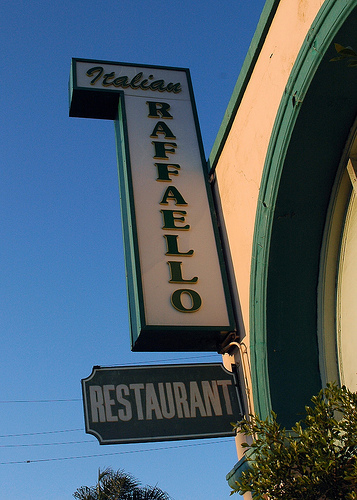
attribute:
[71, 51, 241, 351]
sign — shaped like a seven, green, white, restaurant, advertising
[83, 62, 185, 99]
italian — written in cursive, in cursive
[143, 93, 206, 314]
raffaello — written in print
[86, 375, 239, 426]
lettering — white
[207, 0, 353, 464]
building — green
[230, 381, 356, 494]
tree — green, tropical, leafy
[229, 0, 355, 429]
archway — wooden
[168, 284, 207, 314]
letter o — black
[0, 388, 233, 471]
power lines — strung through air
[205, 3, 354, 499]
exterior wall — painted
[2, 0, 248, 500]
sky — clear, blue, cloudless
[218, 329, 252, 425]
pole — metal